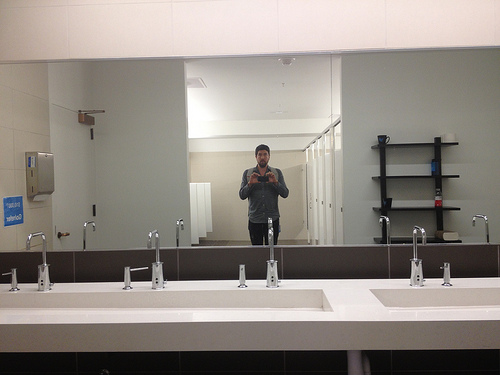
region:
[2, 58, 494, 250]
mirror for viewing one's reflection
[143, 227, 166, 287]
faucet for water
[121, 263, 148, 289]
soap for cleansing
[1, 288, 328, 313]
long sink for multiple people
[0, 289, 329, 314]
sink to hold water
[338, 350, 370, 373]
pipes for water flow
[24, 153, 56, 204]
napkins for hand drying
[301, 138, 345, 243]
bathroom stalls for disposing of human fecal matter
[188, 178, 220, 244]
urinal stalls for privacy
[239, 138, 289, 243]
man taking selfie in bathroom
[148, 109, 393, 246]
a man taking a picture of himself in a bathroom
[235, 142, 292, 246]
a man holding a camera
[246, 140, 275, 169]
a man with a beard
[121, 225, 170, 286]
a faucet in a public restroom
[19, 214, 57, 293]
a faucet in a public restroom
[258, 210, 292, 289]
a faucet in a public restroom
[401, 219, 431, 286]
a faucet in a public restroom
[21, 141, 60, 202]
a hand towel dispenser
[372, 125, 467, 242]
a shelf in a public restroom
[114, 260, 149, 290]
the soap dispenser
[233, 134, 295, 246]
dude with faraway selfie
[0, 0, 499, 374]
some fancy public bathroom somewhere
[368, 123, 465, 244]
an empty slightly fancier than ikea-looking black shelf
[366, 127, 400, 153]
black shelf is primarily empty, other than a single affectedly placed coffee cup.....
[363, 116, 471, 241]
.....and a few bottles, i think, of cleaner, another cup & a large book of some sort for no reason & about to get wet, also for no reason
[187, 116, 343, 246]
the multiple spotless white doors of restrooms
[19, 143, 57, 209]
unmechanical paper towel box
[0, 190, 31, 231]
a sign, mirrored words backwards & unreadable, in white on blue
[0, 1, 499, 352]
sink & its overhead wall are a very light pastel lavender-pink, better to frame the mirror for selfies with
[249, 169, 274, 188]
the camera, which may well be a cellphone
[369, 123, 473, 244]
shelves against the wall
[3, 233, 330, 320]
long sink with several faucets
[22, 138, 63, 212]
paper towel dispenser on the wall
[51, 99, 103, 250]
white door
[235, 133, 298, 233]
man is taking a picture in the bathroom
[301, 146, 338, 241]
bathroom stalls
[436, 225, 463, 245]
paper towels on the shelf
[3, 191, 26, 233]
blue and white sign on the wall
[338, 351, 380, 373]
pipe running under the sink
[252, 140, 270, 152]
man is wearing a hat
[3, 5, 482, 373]
a bathroom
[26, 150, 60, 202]
a paper towel dispenser on the wall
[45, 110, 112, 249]
the door of the bathroom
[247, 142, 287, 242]
a man taking a picture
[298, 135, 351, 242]
stalls in the bathroom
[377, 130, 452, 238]
a shelf against the wall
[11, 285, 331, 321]
the sink of the bathroom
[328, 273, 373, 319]
the white counter top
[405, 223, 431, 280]
a faucet on the sink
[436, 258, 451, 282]
the soap dispenser on the sink